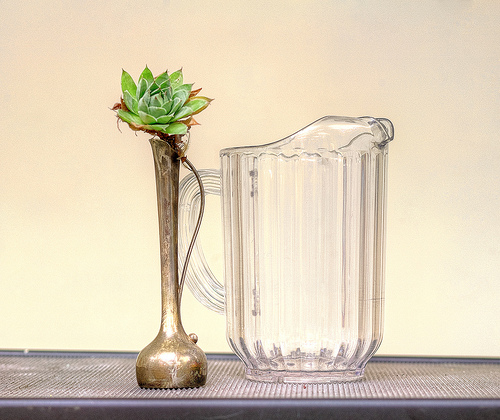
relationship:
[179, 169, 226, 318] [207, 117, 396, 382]
handle of pitcher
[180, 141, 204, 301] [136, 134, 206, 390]
handle of vase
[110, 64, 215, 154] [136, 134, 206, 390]
flower in vase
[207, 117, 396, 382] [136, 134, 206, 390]
pitcher beside vase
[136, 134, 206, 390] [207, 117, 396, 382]
vase sitting beside pitcher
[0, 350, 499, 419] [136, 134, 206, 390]
table holding up vase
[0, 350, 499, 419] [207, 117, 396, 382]
table holding up pitcher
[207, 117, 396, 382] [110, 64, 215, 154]
pitcher used for flower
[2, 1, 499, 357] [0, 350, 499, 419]
wall behind table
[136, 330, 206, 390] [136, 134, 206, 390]
base of vase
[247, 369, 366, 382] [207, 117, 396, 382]
base of pitcher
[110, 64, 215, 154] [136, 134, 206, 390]
flower inside of vase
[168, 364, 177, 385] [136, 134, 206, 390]
mark on vase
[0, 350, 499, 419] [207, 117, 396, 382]
table underneath pitcher